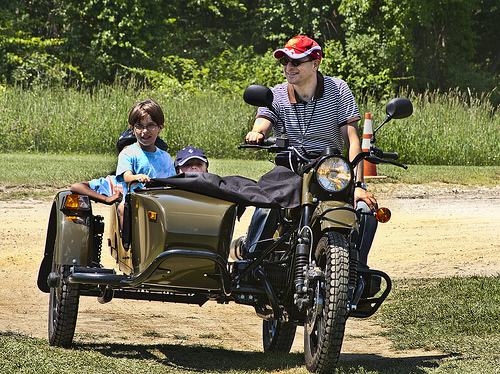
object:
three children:
[70, 97, 213, 255]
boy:
[113, 94, 180, 195]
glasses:
[129, 121, 159, 136]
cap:
[169, 145, 217, 170]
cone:
[359, 109, 381, 179]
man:
[243, 33, 382, 216]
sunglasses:
[274, 54, 317, 68]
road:
[398, 185, 500, 275]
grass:
[0, 146, 106, 175]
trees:
[350, 0, 500, 93]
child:
[171, 144, 217, 179]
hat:
[262, 31, 324, 64]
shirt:
[248, 73, 366, 162]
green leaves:
[87, 19, 134, 60]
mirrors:
[237, 79, 279, 113]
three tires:
[46, 225, 355, 369]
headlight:
[307, 150, 362, 195]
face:
[131, 114, 161, 149]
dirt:
[416, 206, 479, 265]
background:
[0, 76, 499, 181]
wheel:
[38, 210, 89, 350]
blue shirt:
[112, 142, 182, 185]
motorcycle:
[234, 85, 415, 373]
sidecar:
[36, 161, 306, 359]